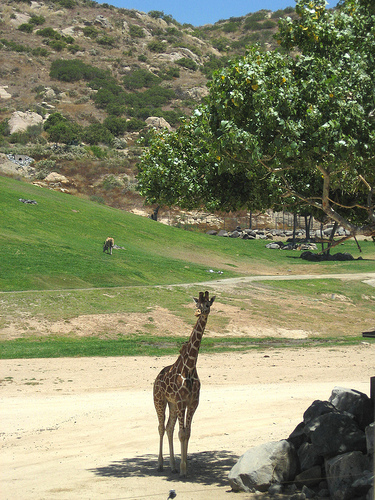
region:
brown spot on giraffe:
[199, 318, 207, 328]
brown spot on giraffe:
[194, 323, 202, 332]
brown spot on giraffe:
[189, 330, 197, 342]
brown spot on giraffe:
[196, 329, 203, 339]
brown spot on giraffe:
[193, 340, 201, 350]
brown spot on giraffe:
[185, 341, 193, 353]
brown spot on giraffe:
[187, 345, 196, 356]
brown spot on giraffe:
[181, 351, 186, 362]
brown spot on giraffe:
[184, 354, 193, 366]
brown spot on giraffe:
[174, 374, 183, 389]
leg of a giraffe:
[151, 417, 166, 464]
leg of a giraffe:
[165, 432, 176, 467]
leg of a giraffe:
[174, 435, 183, 474]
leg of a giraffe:
[181, 432, 193, 475]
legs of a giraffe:
[146, 426, 209, 470]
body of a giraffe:
[136, 353, 202, 409]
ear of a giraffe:
[190, 292, 198, 301]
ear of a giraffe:
[209, 292, 218, 310]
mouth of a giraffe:
[190, 310, 207, 318]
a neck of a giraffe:
[182, 319, 217, 353]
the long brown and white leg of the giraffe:
[151, 394, 166, 474]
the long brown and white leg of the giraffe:
[163, 397, 178, 470]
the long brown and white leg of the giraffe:
[175, 396, 188, 476]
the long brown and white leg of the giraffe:
[184, 395, 197, 475]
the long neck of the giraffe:
[177, 315, 207, 366]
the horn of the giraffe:
[198, 290, 204, 298]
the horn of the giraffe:
[205, 287, 208, 297]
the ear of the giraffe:
[192, 295, 197, 301]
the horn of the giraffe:
[210, 294, 214, 303]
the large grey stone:
[226, 440, 289, 491]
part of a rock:
[360, 416, 368, 422]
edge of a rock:
[308, 449, 310, 458]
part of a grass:
[291, 320, 299, 336]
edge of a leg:
[177, 435, 192, 453]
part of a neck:
[190, 361, 191, 364]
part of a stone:
[301, 446, 308, 462]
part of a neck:
[193, 367, 201, 378]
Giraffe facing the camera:
[153, 290, 217, 482]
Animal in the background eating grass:
[100, 236, 115, 255]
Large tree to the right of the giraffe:
[133, 7, 373, 238]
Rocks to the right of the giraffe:
[228, 386, 372, 496]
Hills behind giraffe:
[2, 2, 370, 211]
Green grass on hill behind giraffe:
[2, 174, 374, 344]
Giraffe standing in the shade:
[86, 289, 238, 493]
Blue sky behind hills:
[109, 2, 343, 29]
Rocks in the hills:
[1, 81, 176, 139]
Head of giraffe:
[190, 291, 217, 317]